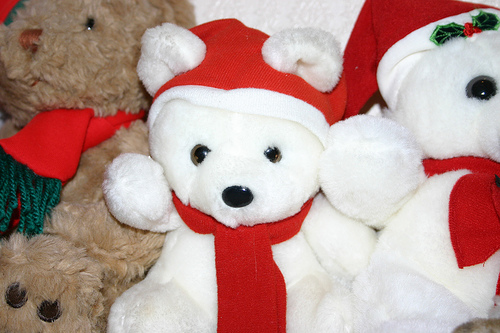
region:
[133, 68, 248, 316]
the stuffed toy is white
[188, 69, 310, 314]
the stuffed toy is white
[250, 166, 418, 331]
the stuffed toy is white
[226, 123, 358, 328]
the stuffed toy is white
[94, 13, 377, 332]
The white bear in the middle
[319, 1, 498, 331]
The bear on the right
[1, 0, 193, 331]
The brown bear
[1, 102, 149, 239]
The red and green scarf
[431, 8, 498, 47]
The mistletoe on a bear's hat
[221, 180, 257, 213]
The nose of the middle bear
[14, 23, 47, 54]
The nose of the brown bear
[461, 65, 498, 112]
The eye of the bear on the right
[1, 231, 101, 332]
The foot of the brown bear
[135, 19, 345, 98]
The ears of the middle bear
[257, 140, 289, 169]
black eye on stuffed animal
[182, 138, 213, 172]
black eye on stuffed animal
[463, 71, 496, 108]
black eye on stuffed animal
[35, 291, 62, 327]
black eye on stuffed animal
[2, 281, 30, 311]
black eye on stuffed animal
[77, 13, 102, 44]
black eye on stuffed animal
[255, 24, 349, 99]
white ear of a stuffed animal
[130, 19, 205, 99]
white ear of a stuffed animal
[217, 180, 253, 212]
black nose of a stuffed animal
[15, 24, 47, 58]
nose of a stuffed animal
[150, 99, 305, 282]
The stuffed bear is white.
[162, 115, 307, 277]
the stuffed bear is wearing a red scarf.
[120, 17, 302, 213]
The teddy bear has a red hat.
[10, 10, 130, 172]
The teddy bear is brown.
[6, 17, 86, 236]
The brown bear has a red and green scarf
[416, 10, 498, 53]
Mistle toe patch decorates the white rim of the hat.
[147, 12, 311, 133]
the hat has a white rim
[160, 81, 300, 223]
the bear has a black nose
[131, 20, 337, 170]
The white teddy bear has two ears.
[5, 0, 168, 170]
the bear has a brown nose.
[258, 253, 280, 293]
edge of a ribbon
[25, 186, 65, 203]
part of an band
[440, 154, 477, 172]
edge of a band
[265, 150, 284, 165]
part of an eye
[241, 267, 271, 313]
part of a shawl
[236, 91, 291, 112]
edge of a marvin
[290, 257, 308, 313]
part of a pocket